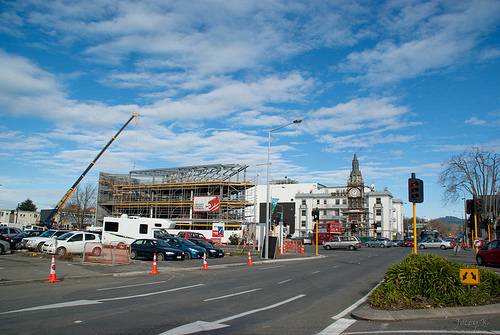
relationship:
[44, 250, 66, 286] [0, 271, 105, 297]
cone near curb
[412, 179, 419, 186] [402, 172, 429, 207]
traffic light on sign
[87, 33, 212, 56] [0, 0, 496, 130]
cloud in sky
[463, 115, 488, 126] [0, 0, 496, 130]
cloud in sky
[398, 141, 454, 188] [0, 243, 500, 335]
ground on street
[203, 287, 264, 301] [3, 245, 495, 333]
line on road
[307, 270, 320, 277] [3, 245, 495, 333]
line on road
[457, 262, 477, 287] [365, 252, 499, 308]
sign in bushes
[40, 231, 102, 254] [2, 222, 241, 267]
car in parking lot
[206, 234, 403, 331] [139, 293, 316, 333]
street with arrow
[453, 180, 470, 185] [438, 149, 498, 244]
limb on tree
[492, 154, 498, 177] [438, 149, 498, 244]
limb on tree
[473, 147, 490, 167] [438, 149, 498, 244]
limb on tree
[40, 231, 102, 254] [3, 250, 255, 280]
car in parking lot